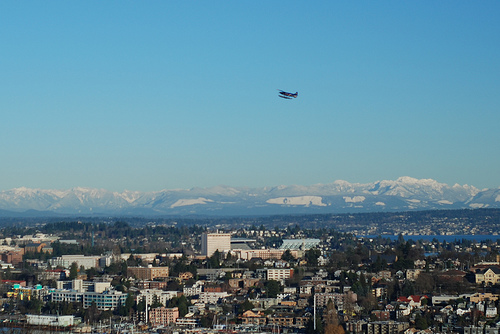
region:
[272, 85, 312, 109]
plane in the sky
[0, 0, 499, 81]
the clear blue sky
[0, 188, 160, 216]
mountains in the background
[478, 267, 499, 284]
yellow house in town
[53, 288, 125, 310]
large building on land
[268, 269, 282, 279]
windows on the building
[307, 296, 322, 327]
tall pole on the ground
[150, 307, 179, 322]
peach building on land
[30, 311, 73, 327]
white building on the ground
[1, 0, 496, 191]
A sky is blue.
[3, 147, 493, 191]
Haze is over the mountains.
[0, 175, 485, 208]
Mountains have white caps.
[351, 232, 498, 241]
Blue water is on the ground.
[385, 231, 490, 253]
Green trees are in front of the water.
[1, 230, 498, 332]
Buildings are part of a city.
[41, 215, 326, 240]
Pine trees are near city buildings.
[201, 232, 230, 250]
A building is white and in the sun.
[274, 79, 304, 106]
plane in the sky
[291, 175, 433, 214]
snow covered mountains beyond the city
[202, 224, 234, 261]
tall white building in the city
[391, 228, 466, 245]
body of water in the city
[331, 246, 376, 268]
trees in the city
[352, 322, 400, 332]
group of buildings in the city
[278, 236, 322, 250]
roof of the building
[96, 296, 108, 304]
windows on the building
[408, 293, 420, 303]
red roof on the house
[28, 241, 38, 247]
gray roof on the building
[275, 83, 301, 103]
an airplane in the sky.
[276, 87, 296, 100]
an airplane in the sky.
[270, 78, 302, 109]
the plane in the air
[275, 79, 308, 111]
the black plane flying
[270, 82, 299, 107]
the airplane flying over the city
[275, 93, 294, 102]
the landing gear for water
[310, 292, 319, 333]
a white pole in the city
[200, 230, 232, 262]
the tallest building in the city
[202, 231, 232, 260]
the white high rise building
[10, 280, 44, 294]
the green mounds on top of the building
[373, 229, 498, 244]
the water in the middle of the city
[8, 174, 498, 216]
the snow covered tops of the mountains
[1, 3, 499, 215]
snowy mountains under a blue sky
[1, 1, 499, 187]
airplane in a blue sky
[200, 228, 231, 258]
off white building is tall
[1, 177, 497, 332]
mountains behind city